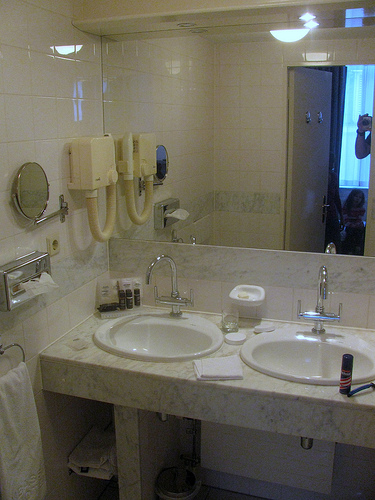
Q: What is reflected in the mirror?
A: A child and an adult taking a picture.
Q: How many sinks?
A: Two.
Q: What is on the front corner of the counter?
A: A razor and shaving cream.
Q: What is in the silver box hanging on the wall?
A: Tissue.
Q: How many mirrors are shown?
A: Two.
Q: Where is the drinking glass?
A: Between the sinks.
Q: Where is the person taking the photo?
A: Behind the open door.